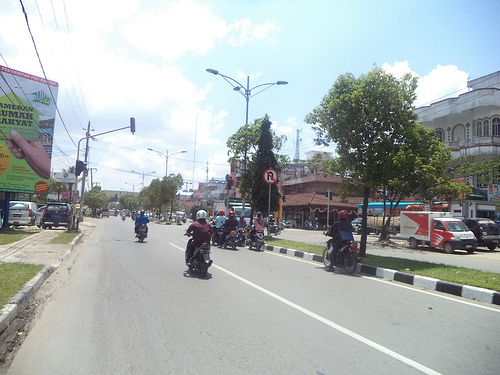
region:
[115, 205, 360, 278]
the people riding on motorcycles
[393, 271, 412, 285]
the black paint on the curb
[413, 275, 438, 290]
the white paint on the curb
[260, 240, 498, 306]
the black and white paint on the curb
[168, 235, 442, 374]
the white line on the road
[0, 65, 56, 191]
the large billboard on the side of the street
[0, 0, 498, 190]
the white clouds in the sky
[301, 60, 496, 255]
the tree on the side of the road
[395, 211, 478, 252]
the red and white truck in the parking lot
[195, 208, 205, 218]
the white helmet on the person's head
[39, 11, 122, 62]
white clouds in blue sky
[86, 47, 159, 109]
white clouds in blue sky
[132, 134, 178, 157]
white clouds in blue sky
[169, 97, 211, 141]
white clouds in blue sky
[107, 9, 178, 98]
white clouds in blue sky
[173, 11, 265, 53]
white clouds in blue sky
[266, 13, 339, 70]
white clouds in blue sky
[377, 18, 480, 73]
white clouds in blue sky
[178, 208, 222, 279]
motorcycle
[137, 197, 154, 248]
person riding motorcycle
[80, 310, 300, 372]
The street is made of asphalt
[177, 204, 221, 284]
A man riding a motorcycle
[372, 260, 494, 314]
The sidewalk is black and white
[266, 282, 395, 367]
The line in the middle of the street is white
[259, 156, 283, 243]
The sign on the side of the road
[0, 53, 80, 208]
A billboard on the side of the road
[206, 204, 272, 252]
A group of people riding motorcycles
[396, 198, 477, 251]
A truck parked on the side of the road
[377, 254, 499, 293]
The side is the road has grass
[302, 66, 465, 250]
The tree is tall with green leaves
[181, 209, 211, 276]
the motorcyclist is on the road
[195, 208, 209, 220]
the cyclist is wearing a helmet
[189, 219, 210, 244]
the cyclist is wearing a shirt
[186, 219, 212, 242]
the shirt is burgundy in color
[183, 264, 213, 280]
the cyclist is casting a shadow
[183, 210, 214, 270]
a man is riding a motorcycle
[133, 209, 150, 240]
a man is riding a motorcycle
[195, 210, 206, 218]
the helmet is white in color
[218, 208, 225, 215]
the man is wearing a helmet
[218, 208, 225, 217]
the helmet is red in color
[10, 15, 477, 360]
commercial streets in a town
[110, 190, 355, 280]
motorcyclists driving down gray road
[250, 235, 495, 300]
black and white border on curb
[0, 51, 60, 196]
large billboard with hand holding object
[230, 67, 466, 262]
green trees growing in median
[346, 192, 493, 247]
bus and trucks on road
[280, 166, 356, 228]
brown building with ruffled awning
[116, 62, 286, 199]
row of poles dividing into two street lamps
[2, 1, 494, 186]
white clouds in blue sky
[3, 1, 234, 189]
elevated wires curving across road